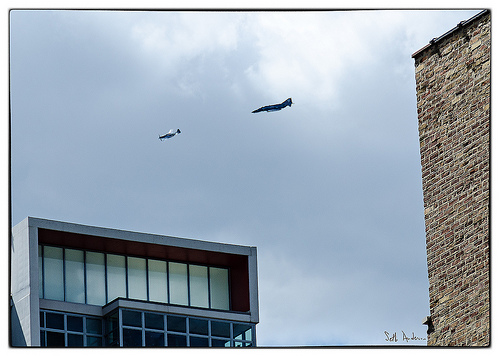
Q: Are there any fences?
A: No, there are no fences.